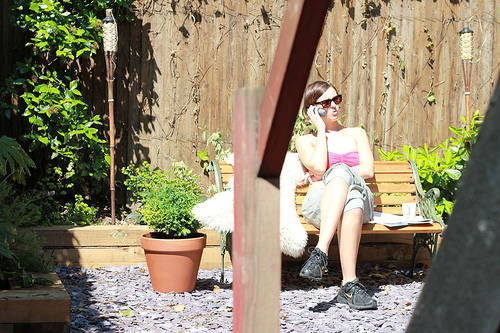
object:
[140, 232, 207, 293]
flower pot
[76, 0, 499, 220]
fence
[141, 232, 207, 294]
pot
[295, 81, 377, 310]
she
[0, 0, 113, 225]
plants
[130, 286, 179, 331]
ground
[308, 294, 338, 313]
shadows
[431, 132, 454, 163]
ground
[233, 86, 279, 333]
red column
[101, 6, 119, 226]
torch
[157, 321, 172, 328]
rock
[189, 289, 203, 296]
rock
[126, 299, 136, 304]
rock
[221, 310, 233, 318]
rock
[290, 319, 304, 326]
rock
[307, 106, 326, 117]
phone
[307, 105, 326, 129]
hand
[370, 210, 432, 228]
paper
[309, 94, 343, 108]
sunglasses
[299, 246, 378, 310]
black shoes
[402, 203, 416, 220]
cup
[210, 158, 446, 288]
bench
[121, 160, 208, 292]
plant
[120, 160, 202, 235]
bush